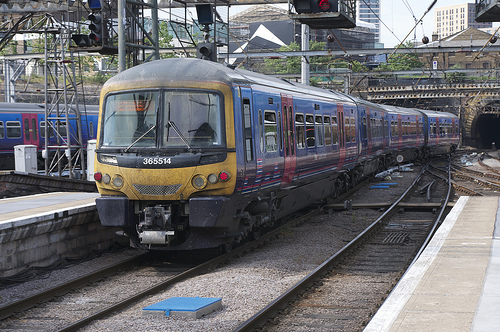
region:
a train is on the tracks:
[91, 55, 459, 256]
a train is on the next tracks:
[0, 101, 95, 173]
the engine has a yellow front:
[90, 55, 235, 207]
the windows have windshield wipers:
[105, 88, 226, 154]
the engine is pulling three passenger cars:
[96, 55, 461, 242]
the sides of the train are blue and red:
[235, 72, 461, 217]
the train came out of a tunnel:
[100, 55, 498, 246]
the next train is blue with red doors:
[0, 100, 95, 180]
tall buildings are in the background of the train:
[140, 5, 496, 207]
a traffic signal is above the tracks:
[65, 2, 120, 59]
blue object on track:
[139, 289, 234, 326]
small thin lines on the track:
[314, 285, 376, 330]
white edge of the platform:
[396, 246, 456, 300]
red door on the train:
[270, 89, 303, 180]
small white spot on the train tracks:
[75, 286, 105, 304]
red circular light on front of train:
[214, 166, 252, 200]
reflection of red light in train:
[109, 95, 159, 117]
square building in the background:
[420, 4, 475, 57]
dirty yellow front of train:
[86, 74, 288, 219]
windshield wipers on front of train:
[114, 93, 220, 162]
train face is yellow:
[76, 65, 251, 267]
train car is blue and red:
[238, 72, 490, 181]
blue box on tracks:
[136, 276, 208, 326]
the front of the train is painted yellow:
[90, 52, 235, 217]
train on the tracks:
[65, 35, 480, 245]